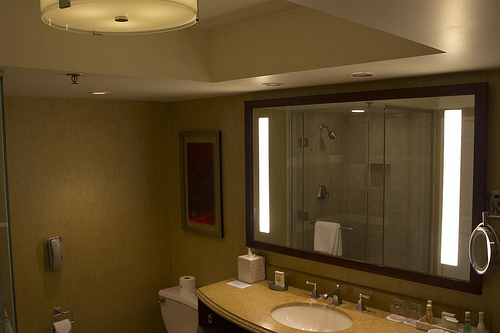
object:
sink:
[270, 302, 354, 332]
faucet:
[322, 284, 342, 305]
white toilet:
[158, 286, 198, 332]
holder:
[51, 306, 75, 327]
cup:
[390, 299, 407, 321]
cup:
[406, 303, 423, 325]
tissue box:
[237, 254, 265, 284]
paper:
[179, 276, 195, 294]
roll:
[179, 276, 196, 294]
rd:
[226, 280, 252, 290]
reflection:
[253, 94, 474, 284]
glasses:
[388, 293, 407, 321]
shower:
[320, 123, 337, 139]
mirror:
[252, 94, 476, 284]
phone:
[44, 236, 65, 272]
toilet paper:
[207, 220, 217, 288]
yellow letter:
[44, 235, 66, 271]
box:
[238, 255, 266, 283]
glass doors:
[290, 108, 432, 273]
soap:
[445, 318, 458, 331]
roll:
[237, 254, 265, 284]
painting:
[178, 130, 224, 239]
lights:
[37, 0, 199, 36]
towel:
[313, 221, 342, 257]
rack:
[309, 220, 357, 232]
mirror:
[468, 223, 497, 275]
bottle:
[425, 300, 433, 324]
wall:
[2, 94, 170, 333]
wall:
[169, 69, 500, 333]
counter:
[194, 277, 491, 333]